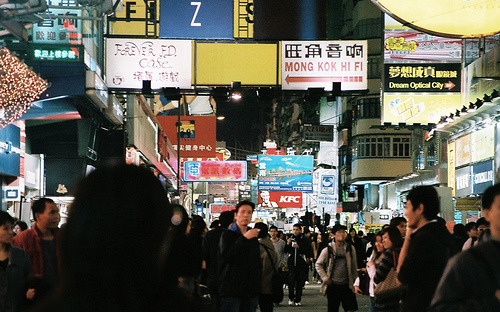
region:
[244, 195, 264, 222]
face of a man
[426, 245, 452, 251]
back of a man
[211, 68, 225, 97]
part of a board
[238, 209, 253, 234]
face of a man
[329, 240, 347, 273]
part of a jacket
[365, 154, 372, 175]
part of a building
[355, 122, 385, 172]
edge of a building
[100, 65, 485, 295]
Downtown area of a big city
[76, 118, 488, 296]
People walking around in a city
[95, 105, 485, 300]
People are enjoying the nightlife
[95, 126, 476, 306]
People are shopping at night time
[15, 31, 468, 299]
People are enjoying themselves after work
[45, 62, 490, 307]
People are looking for good bargains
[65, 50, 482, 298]
People are in an Asian city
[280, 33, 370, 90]
A sign in a city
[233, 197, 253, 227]
The head of a person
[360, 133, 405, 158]
The Windows on a building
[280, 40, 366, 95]
a sign with writing in two languages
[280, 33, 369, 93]
a white sign with black and red letters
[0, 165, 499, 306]
a large crowd of people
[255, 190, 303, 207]
a sign for kfc in the distance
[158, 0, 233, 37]
a blue sign that says z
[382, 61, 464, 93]
a black sign with yellow words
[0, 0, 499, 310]
a street filled with people and advertisements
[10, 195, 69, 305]
a man wearing a red shirt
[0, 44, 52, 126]
a bunch of christmas light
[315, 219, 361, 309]
a person wearing a white jacket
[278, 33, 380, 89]
a big red and black sign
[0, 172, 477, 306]
a bunch of people walking around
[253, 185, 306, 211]
a KFC sign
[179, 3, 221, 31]
a white letter z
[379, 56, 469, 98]
a sign for dream optical city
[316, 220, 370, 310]
a man smoking a cigerette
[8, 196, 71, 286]
a man in a red jacket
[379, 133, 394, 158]
a window in a building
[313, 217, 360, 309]
a man wearing a backpack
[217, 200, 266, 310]
a man with a black jacket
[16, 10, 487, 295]
people and colorful signs on a crowded street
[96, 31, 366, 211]
elevated signs in English and Chinese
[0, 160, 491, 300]
men and women wearing gray and black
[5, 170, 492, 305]
people on commercial street standing and socializing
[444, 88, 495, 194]
flat panel of many signs under row of lights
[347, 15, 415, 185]
curved building extending into street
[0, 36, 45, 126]
tiny white lights on a panel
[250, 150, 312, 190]
blue sign with buildings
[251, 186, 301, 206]
internationally-recognized red sign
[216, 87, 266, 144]
black sky with two lit downward lights